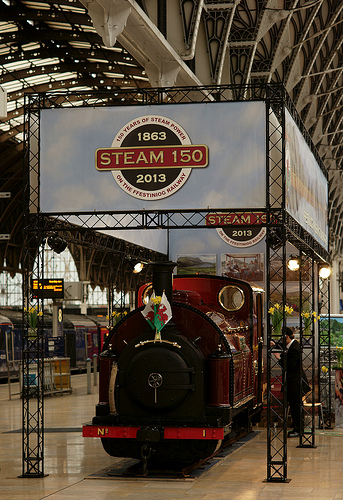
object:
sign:
[32, 278, 65, 299]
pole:
[282, 242, 287, 439]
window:
[219, 285, 245, 313]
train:
[0, 314, 117, 380]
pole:
[20, 219, 44, 477]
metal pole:
[94, 357, 98, 386]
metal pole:
[87, 362, 91, 394]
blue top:
[87, 358, 92, 361]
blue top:
[93, 354, 98, 357]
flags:
[153, 290, 172, 332]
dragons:
[156, 303, 168, 327]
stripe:
[83, 426, 223, 439]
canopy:
[22, 81, 332, 265]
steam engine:
[82, 294, 253, 476]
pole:
[266, 226, 287, 479]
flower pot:
[274, 337, 279, 342]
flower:
[287, 307, 294, 315]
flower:
[285, 305, 290, 313]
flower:
[274, 302, 280, 310]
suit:
[279, 341, 311, 433]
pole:
[317, 264, 332, 427]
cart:
[21, 356, 71, 394]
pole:
[299, 249, 315, 447]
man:
[270, 326, 311, 439]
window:
[0, 238, 130, 306]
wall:
[170, 255, 343, 319]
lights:
[287, 260, 300, 272]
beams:
[284, 210, 333, 268]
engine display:
[82, 262, 256, 478]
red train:
[82, 273, 266, 479]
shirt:
[285, 339, 295, 351]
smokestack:
[147, 259, 176, 303]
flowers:
[268, 307, 275, 315]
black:
[116, 400, 214, 426]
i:
[203, 429, 205, 436]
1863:
[138, 132, 167, 141]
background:
[0, 0, 343, 275]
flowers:
[304, 312, 310, 319]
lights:
[318, 267, 332, 279]